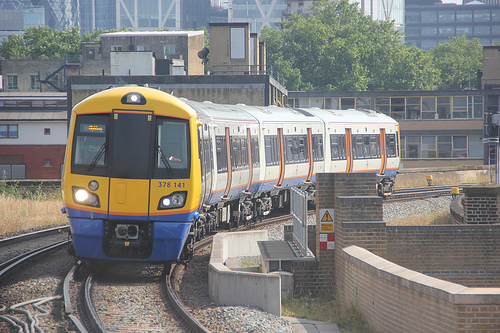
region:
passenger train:
[56, 75, 417, 280]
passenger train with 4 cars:
[58, 70, 413, 264]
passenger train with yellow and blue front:
[58, 67, 403, 268]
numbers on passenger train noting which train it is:
[155, 179, 189, 193]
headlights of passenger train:
[68, 174, 185, 219]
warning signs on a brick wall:
[314, 206, 336, 253]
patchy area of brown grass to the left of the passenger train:
[3, 193, 68, 225]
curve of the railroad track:
[58, 257, 201, 331]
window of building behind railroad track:
[450, 132, 467, 158]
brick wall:
[316, 169, 495, 316]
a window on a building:
[405, 7, 422, 25]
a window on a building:
[420, 8, 440, 27]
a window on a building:
[436, 7, 455, 25]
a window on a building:
[453, 7, 475, 22]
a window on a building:
[470, 5, 491, 24]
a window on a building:
[403, 22, 422, 41]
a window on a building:
[421, 21, 438, 38]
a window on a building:
[446, 94, 463, 118]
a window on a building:
[436, 133, 449, 161]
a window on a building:
[449, 132, 466, 157]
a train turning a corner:
[46, 61, 424, 289]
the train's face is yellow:
[51, 66, 201, 271]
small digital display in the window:
[78, 115, 114, 140]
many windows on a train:
[66, 103, 409, 191]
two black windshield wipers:
[72, 128, 185, 193]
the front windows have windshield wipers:
[74, 111, 198, 196]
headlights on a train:
[66, 176, 196, 221]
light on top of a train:
[112, 90, 157, 111]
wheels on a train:
[151, 166, 401, 270]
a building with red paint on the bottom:
[0, 88, 100, 193]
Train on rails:
[53, 76, 409, 281]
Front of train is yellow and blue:
[56, 76, 206, 278]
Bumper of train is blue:
[56, 210, 198, 268]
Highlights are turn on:
[65, 183, 97, 206]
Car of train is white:
[193, 91, 408, 216]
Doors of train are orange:
[221, 121, 400, 196]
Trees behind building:
[258, 0, 487, 100]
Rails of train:
[8, 253, 206, 325]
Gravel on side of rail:
[198, 302, 289, 332]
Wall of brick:
[311, 163, 499, 330]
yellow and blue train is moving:
[60, 85, 402, 264]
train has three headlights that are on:
[75, 94, 171, 207]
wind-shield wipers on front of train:
[87, 140, 174, 176]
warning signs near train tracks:
[317, 206, 334, 250]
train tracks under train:
[62, 185, 498, 331]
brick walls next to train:
[267, 170, 498, 331]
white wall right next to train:
[208, 229, 281, 316]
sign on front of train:
[77, 123, 107, 133]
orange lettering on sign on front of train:
[88, 124, 101, 132]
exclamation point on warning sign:
[324, 211, 328, 222]